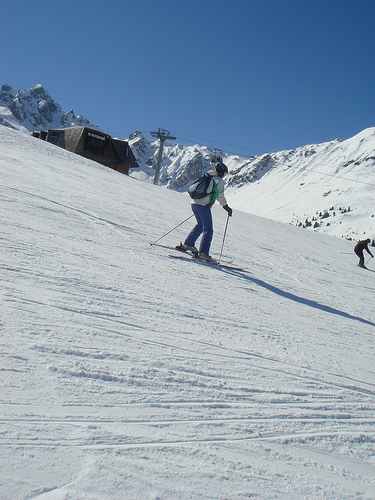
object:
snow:
[0, 146, 375, 494]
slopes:
[167, 147, 374, 246]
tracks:
[0, 386, 375, 459]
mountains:
[0, 74, 375, 187]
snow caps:
[3, 80, 65, 107]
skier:
[179, 159, 233, 266]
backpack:
[188, 170, 212, 198]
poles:
[217, 207, 233, 265]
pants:
[185, 199, 214, 255]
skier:
[353, 236, 375, 272]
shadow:
[209, 258, 373, 327]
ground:
[0, 273, 375, 495]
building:
[38, 124, 140, 171]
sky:
[0, 3, 374, 157]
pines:
[292, 202, 354, 226]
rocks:
[5, 80, 88, 129]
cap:
[216, 162, 229, 174]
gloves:
[222, 203, 234, 215]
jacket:
[188, 169, 226, 207]